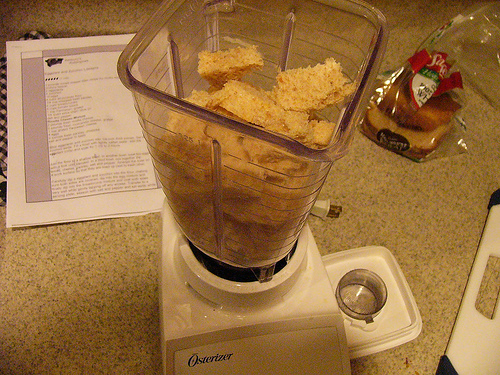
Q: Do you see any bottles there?
A: No, there are no bottles.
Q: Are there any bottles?
A: No, there are no bottles.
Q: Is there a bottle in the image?
A: No, there are no bottles.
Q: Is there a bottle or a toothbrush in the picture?
A: No, there are no bottles or toothbrushes.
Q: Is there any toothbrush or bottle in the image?
A: No, there are no bottles or toothbrushes.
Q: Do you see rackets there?
A: No, there are no rackets.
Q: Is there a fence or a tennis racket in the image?
A: No, there are no rackets or fences.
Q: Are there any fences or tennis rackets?
A: No, there are no tennis rackets or fences.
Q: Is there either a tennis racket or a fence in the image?
A: No, there are no rackets or fences.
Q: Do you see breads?
A: Yes, there is a bread.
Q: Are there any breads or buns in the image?
A: Yes, there is a bread.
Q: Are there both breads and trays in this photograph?
A: No, there is a bread but no trays.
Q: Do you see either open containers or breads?
A: Yes, there is an open bread.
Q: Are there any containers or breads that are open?
A: Yes, the bread is open.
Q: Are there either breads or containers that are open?
A: Yes, the bread is open.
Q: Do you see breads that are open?
A: Yes, there is an open bread.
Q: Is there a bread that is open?
A: Yes, there is a bread that is open.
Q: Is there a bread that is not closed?
A: Yes, there is a open bread.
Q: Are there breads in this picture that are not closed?
A: Yes, there is a open bread.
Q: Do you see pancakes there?
A: No, there are no pancakes.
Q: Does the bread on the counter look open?
A: Yes, the bread is open.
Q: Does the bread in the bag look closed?
A: No, the bread is open.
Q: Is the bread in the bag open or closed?
A: The bread is open.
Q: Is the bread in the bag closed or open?
A: The bread is open.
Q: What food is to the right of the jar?
A: The food is a bread.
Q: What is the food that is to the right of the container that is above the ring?
A: The food is a bread.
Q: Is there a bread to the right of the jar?
A: Yes, there is a bread to the right of the jar.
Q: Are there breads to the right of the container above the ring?
A: Yes, there is a bread to the right of the jar.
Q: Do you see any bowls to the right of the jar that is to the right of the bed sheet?
A: No, there is a bread to the right of the jar.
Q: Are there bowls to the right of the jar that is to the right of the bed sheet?
A: No, there is a bread to the right of the jar.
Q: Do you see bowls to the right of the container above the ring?
A: No, there is a bread to the right of the jar.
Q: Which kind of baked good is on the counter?
A: The food is a bread.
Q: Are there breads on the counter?
A: Yes, there is a bread on the counter.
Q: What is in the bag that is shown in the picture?
A: The bread is in the bag.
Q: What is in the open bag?
A: The bread is in the bag.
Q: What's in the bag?
A: The bread is in the bag.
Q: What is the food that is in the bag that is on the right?
A: The food is a bread.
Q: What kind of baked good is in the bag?
A: The food is a bread.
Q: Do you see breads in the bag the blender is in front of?
A: Yes, there is a bread in the bag.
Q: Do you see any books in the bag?
A: No, there is a bread in the bag.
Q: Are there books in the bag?
A: No, there is a bread in the bag.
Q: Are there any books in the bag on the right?
A: No, there is a bread in the bag.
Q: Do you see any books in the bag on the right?
A: No, there is a bread in the bag.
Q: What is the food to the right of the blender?
A: The food is a bread.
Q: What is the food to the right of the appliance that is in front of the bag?
A: The food is a bread.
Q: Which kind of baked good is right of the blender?
A: The food is a bread.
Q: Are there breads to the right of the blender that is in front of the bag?
A: Yes, there is a bread to the right of the blender.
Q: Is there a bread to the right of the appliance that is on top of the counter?
A: Yes, there is a bread to the right of the blender.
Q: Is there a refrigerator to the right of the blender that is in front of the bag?
A: No, there is a bread to the right of the blender.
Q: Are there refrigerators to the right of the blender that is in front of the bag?
A: No, there is a bread to the right of the blender.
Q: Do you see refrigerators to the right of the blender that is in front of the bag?
A: No, there is a bread to the right of the blender.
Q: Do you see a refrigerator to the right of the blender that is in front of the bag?
A: No, there is a bread to the right of the blender.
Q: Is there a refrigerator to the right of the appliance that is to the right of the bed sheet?
A: No, there is a bread to the right of the blender.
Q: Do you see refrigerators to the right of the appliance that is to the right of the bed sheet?
A: No, there is a bread to the right of the blender.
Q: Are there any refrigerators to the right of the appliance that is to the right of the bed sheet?
A: No, there is a bread to the right of the blender.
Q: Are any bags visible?
A: Yes, there is a bag.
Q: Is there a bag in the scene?
A: Yes, there is a bag.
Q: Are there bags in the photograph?
A: Yes, there is a bag.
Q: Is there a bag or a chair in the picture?
A: Yes, there is a bag.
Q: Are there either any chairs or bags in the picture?
A: Yes, there is a bag.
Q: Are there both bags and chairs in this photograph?
A: No, there is a bag but no chairs.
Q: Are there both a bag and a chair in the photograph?
A: No, there is a bag but no chairs.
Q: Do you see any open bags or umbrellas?
A: Yes, there is an open bag.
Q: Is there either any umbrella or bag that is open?
A: Yes, the bag is open.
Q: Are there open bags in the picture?
A: Yes, there is an open bag.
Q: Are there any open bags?
A: Yes, there is an open bag.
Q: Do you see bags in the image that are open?
A: Yes, there is a bag that is open.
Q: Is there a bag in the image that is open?
A: Yes, there is a bag that is open.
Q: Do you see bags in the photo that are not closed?
A: Yes, there is a open bag.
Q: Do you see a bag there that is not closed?
A: Yes, there is a open bag.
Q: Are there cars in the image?
A: No, there are no cars.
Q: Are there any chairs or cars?
A: No, there are no cars or chairs.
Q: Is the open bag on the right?
A: Yes, the bag is on the right of the image.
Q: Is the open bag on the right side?
A: Yes, the bag is on the right of the image.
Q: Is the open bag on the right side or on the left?
A: The bag is on the right of the image.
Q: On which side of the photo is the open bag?
A: The bag is on the right of the image.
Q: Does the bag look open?
A: Yes, the bag is open.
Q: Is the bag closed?
A: No, the bag is open.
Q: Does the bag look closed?
A: No, the bag is open.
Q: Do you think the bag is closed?
A: No, the bag is open.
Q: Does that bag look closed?
A: No, the bag is open.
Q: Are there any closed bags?
A: No, there is a bag but it is open.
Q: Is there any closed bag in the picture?
A: No, there is a bag but it is open.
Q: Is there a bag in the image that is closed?
A: No, there is a bag but it is open.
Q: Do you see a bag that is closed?
A: No, there is a bag but it is open.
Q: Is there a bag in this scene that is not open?
A: No, there is a bag but it is open.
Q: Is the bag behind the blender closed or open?
A: The bag is open.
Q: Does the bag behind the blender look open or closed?
A: The bag is open.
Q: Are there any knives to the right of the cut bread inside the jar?
A: No, there is a bag to the right of the bread.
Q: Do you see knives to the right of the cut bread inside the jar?
A: No, there is a bag to the right of the bread.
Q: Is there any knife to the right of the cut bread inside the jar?
A: No, there is a bag to the right of the bread.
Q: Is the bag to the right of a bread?
A: Yes, the bag is to the right of a bread.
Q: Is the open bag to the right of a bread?
A: Yes, the bag is to the right of a bread.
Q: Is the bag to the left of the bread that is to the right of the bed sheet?
A: No, the bag is to the right of the bread.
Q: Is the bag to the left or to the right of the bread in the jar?
A: The bag is to the right of the bread.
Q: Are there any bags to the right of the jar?
A: Yes, there is a bag to the right of the jar.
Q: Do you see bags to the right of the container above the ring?
A: Yes, there is a bag to the right of the jar.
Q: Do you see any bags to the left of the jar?
A: No, the bag is to the right of the jar.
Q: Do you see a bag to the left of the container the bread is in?
A: No, the bag is to the right of the jar.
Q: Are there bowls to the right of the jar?
A: No, there is a bag to the right of the jar.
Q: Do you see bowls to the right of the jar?
A: No, there is a bag to the right of the jar.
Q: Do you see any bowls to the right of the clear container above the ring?
A: No, there is a bag to the right of the jar.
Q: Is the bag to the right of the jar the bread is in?
A: Yes, the bag is to the right of the jar.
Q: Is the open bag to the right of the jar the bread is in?
A: Yes, the bag is to the right of the jar.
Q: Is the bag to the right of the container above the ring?
A: Yes, the bag is to the right of the jar.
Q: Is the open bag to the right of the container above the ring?
A: Yes, the bag is to the right of the jar.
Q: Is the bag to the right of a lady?
A: No, the bag is to the right of the jar.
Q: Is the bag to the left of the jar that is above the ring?
A: No, the bag is to the right of the jar.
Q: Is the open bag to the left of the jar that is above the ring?
A: No, the bag is to the right of the jar.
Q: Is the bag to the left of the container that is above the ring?
A: No, the bag is to the right of the jar.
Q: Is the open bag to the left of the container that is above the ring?
A: No, the bag is to the right of the jar.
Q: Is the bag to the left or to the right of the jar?
A: The bag is to the right of the jar.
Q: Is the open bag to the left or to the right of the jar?
A: The bag is to the right of the jar.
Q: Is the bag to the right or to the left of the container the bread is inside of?
A: The bag is to the right of the jar.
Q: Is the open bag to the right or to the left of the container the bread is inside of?
A: The bag is to the right of the jar.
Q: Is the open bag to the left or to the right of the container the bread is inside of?
A: The bag is to the right of the jar.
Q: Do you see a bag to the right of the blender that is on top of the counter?
A: Yes, there is a bag to the right of the blender.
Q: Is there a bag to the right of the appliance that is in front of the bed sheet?
A: Yes, there is a bag to the right of the blender.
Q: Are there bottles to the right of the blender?
A: No, there is a bag to the right of the blender.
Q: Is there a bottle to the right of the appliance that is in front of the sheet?
A: No, there is a bag to the right of the blender.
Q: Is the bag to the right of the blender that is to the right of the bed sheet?
A: Yes, the bag is to the right of the blender.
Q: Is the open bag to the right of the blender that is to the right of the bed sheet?
A: Yes, the bag is to the right of the blender.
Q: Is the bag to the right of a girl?
A: No, the bag is to the right of the blender.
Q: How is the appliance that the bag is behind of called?
A: The appliance is a blender.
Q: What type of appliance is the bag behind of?
A: The bag is behind the blender.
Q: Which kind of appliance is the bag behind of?
A: The bag is behind the blender.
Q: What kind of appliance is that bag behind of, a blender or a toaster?
A: The bag is behind a blender.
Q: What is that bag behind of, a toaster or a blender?
A: The bag is behind a blender.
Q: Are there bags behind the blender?
A: Yes, there is a bag behind the blender.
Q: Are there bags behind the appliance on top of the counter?
A: Yes, there is a bag behind the blender.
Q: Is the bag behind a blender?
A: Yes, the bag is behind a blender.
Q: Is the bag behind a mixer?
A: No, the bag is behind a blender.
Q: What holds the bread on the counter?
A: The bag holds the bread.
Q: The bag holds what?
A: The bag holds the bread.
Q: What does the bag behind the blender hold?
A: The bag holds the bread.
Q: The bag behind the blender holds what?
A: The bag holds the bread.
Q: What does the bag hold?
A: The bag holds the bread.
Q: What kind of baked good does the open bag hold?
A: The bag holds the bread.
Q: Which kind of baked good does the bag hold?
A: The bag holds the bread.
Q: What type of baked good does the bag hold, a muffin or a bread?
A: The bag holds a bread.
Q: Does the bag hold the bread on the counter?
A: Yes, the bag holds the bread.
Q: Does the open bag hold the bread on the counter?
A: Yes, the bag holds the bread.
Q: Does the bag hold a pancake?
A: No, the bag holds the bread.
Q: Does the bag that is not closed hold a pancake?
A: No, the bag holds the bread.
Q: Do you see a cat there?
A: No, there are no cats.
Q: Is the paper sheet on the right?
A: No, the bed sheet is on the left of the image.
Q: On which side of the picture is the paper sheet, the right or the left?
A: The bed sheet is on the left of the image.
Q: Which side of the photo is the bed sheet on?
A: The bed sheet is on the left of the image.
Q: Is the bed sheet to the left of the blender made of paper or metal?
A: The sheet is made of paper.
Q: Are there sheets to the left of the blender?
A: Yes, there is a sheet to the left of the blender.